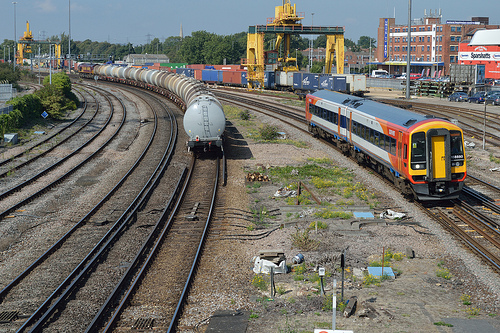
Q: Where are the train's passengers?
A: Inside the train.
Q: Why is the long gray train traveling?
A: To deliver cargo.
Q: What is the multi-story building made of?
A: Brick.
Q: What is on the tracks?
A: A line of box cars.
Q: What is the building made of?
A: Brown bricks.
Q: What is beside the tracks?
A: Green grass and rocks.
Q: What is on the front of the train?
A: Door and lights.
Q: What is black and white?
A: A sign.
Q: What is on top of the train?
A: A silver roof.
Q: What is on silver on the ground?
A: Long cables.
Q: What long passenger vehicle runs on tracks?
A: Train.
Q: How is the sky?
A: Clear.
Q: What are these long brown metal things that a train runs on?
A: Tracks.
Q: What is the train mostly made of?
A: Metal.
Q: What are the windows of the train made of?
A: Glass.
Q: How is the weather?
A: Sunny.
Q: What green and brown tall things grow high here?
A: Trees.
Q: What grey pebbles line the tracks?
A: Gravel.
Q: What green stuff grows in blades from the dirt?
A: Grass.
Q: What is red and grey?
A: Train.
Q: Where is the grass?
A: In between tracks.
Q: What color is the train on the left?
A: Gray.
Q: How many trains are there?
A: Two.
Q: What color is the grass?
A: Green.